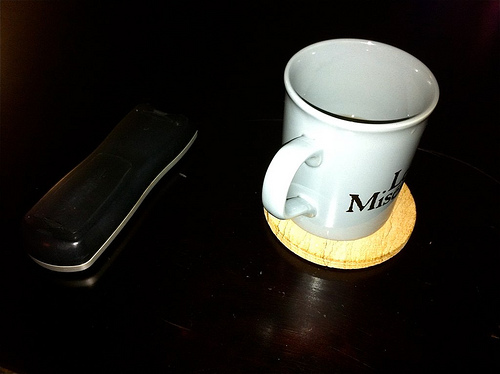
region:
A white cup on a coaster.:
[260, 35, 446, 239]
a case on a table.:
[24, 115, 224, 287]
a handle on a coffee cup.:
[259, 138, 335, 230]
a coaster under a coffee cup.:
[261, 165, 423, 277]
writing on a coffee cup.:
[341, 167, 400, 218]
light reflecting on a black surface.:
[58, 230, 101, 261]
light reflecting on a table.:
[284, 271, 344, 331]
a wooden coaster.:
[258, 167, 431, 275]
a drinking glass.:
[252, 45, 454, 238]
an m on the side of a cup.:
[338, 184, 384, 222]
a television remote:
[8, 95, 215, 286]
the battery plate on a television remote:
[44, 149, 134, 235]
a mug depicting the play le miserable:
[261, 27, 445, 273]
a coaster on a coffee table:
[260, 157, 425, 273]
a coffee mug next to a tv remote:
[8, 29, 448, 279]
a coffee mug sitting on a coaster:
[258, 33, 433, 275]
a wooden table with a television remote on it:
[2, 4, 237, 373]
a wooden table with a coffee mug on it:
[230, 2, 482, 370]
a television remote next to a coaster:
[2, 90, 442, 290]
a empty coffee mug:
[231, 25, 430, 238]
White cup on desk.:
[252, 35, 440, 242]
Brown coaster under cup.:
[255, 166, 422, 273]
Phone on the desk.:
[17, 95, 207, 280]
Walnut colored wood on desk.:
[2, 0, 495, 372]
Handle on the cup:
[260, 133, 322, 221]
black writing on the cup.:
[343, 163, 406, 217]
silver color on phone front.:
[21, 95, 199, 275]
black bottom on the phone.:
[16, 90, 206, 275]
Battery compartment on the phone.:
[34, 143, 136, 243]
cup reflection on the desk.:
[238, 243, 358, 359]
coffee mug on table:
[253, 43, 429, 248]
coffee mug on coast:
[237, 36, 454, 279]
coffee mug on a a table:
[246, 26, 453, 284]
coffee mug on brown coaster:
[258, 37, 468, 282]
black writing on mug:
[338, 163, 417, 230]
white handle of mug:
[268, 127, 335, 229]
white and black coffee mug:
[242, 34, 446, 231]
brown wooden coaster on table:
[293, 227, 425, 274]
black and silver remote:
[0, 66, 216, 309]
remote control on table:
[23, 97, 208, 280]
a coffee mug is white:
[262, 37, 441, 242]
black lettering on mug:
[345, 170, 403, 214]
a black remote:
[24, 103, 204, 278]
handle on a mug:
[263, 137, 313, 222]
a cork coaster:
[261, 167, 415, 265]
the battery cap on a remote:
[35, 152, 130, 233]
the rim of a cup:
[285, 35, 441, 131]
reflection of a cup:
[265, 264, 353, 350]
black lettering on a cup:
[345, 168, 405, 217]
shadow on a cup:
[300, 96, 421, 123]